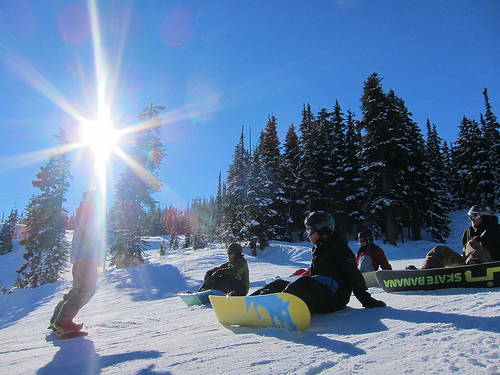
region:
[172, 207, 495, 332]
People sitting on the snow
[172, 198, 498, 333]
Snow boarders sitting on the snow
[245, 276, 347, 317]
Man is wearing pants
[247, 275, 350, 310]
Man is wearing black pants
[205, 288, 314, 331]
Man has a snowboard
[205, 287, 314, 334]
Man has a yellow and blue snowboard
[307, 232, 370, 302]
Man is wearing a jacket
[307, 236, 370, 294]
Man is wearing a black jacket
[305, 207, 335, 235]
Man is wearing a helmet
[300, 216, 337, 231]
Man is wearing goggles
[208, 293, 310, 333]
Yellow and blue snowboard.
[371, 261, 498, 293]
Black and green snowboard.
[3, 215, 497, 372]
White snow on the ground.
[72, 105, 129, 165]
Sun in the sky.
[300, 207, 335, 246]
Goggles on the head.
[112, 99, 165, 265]
Tree in the background.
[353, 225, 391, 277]
Red and gray jacket on the person.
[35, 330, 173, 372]
Shadow of skier on the ground.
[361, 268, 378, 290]
White snowboard on the ground.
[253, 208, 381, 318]
Black snowsuit on the ground.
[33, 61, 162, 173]
sun glare between two trees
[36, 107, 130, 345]
snowboarder standing in glare of sun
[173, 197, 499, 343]
snowboarders sitting in snow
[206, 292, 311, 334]
yellow and blue snowboard in snow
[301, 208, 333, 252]
person wearing dark helmet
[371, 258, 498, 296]
black and green snowboard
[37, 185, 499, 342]
man standing in front of seated snowboarders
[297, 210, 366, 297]
man wearing dark coat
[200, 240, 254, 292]
man sitting crouched in the snow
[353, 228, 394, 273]
man wearing red and gray jacket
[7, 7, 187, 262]
white sun generating circle of rays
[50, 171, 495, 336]
person standing in front of seated skateboarders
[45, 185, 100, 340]
person leaning forward with heels above snow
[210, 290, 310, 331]
yellow snowboard with blue four-legged animal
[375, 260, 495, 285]
black snowboard with yellow writing and angles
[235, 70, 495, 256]
cone-shaped evergreens with snow on branches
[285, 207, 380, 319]
person leaning back on hands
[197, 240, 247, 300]
person with hands over knees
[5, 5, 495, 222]
clear deep-blue sky over slope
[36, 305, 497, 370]
shadows to side of snowboarders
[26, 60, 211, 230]
The glare from the sun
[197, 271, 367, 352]
The man has a yellow snowboard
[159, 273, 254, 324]
The man has a green and blue snowboard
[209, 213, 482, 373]
The man is sitting on snow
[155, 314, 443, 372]
The ground is covered in snow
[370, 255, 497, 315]
Writing is on the bottom of the snowboard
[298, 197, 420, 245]
The man is wearing a helmet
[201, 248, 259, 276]
The man is wearing sunglasses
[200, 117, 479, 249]
The trees are covered in snow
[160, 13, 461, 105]
The sky is blue and clear